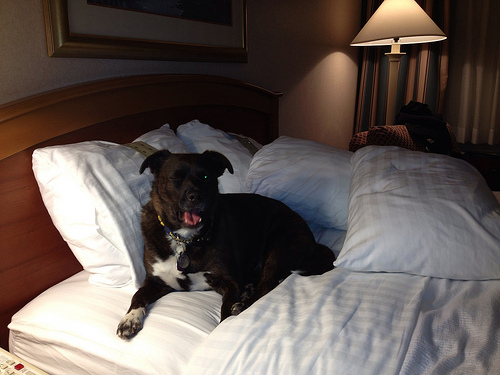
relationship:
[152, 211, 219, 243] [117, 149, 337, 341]
collar on dog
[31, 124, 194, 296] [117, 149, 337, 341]
pillow beside dog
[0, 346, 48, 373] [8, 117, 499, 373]
phone next to bed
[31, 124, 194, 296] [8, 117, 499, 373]
pillow on bed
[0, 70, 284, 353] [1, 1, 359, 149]
headboard against wall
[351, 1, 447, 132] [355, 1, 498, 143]
curtain over window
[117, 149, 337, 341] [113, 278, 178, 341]
dog has leg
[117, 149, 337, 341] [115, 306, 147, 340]
dog has paw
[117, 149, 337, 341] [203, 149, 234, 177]
dog has ear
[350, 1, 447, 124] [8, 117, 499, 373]
lamp next to bed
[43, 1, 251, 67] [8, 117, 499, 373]
painting over bed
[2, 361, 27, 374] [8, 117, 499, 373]
buttons beside bed